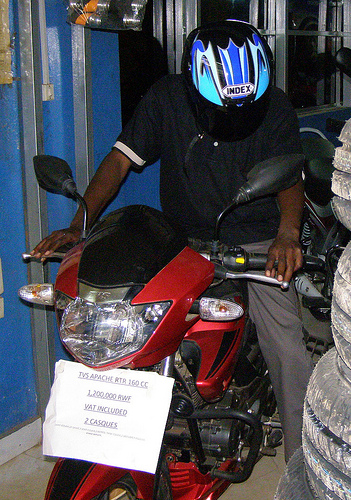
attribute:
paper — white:
[42, 359, 175, 475]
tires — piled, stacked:
[275, 116, 351, 499]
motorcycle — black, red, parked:
[17, 155, 325, 499]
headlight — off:
[50, 289, 171, 370]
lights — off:
[18, 283, 244, 360]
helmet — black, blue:
[182, 18, 275, 142]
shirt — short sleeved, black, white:
[111, 75, 303, 245]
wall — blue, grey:
[1, 0, 351, 466]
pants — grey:
[232, 237, 315, 466]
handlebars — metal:
[22, 245, 326, 289]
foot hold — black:
[194, 408, 264, 483]